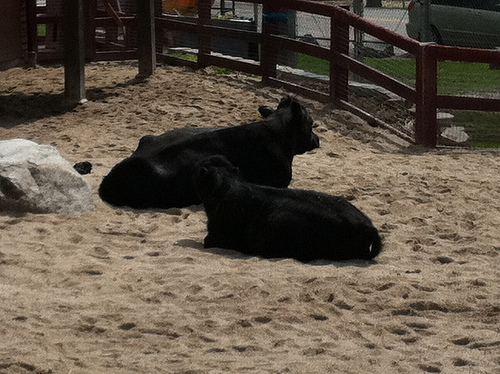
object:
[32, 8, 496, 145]
region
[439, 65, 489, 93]
grass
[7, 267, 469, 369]
sand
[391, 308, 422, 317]
footprints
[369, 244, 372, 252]
white hair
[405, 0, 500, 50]
van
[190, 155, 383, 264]
cow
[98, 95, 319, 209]
black cow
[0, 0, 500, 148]
fence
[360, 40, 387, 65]
net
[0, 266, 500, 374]
dirt